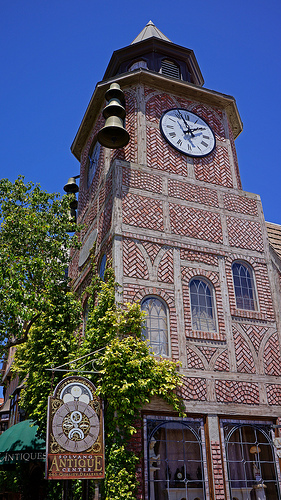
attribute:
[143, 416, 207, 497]
glass windows — circle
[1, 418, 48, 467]
awning — green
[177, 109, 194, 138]
hand — black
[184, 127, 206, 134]
hand — black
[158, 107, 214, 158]
clock — white, round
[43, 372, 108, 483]
sign — antique store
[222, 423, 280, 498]
window — glass, semi circle shaped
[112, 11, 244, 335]
tower — brick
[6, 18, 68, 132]
sky — blue, clear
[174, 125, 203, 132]
hand — hour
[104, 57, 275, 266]
building — Scandinavian-influenced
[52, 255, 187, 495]
ivy — lush, green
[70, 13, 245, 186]
tower — red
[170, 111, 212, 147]
face — white